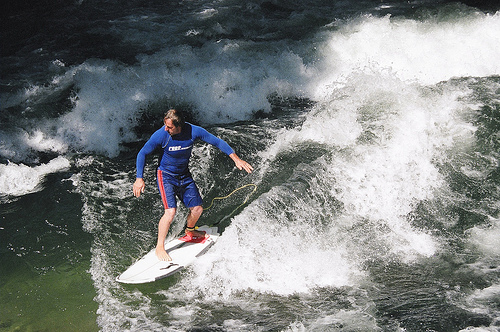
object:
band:
[184, 225, 199, 232]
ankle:
[182, 226, 196, 231]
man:
[131, 108, 254, 262]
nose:
[162, 125, 168, 133]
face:
[162, 115, 175, 135]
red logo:
[177, 230, 209, 244]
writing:
[170, 146, 178, 152]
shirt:
[134, 122, 236, 178]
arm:
[193, 126, 240, 163]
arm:
[134, 134, 159, 179]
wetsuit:
[134, 120, 236, 175]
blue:
[134, 121, 235, 178]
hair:
[163, 107, 184, 133]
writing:
[175, 144, 181, 151]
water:
[0, 0, 499, 331]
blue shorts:
[155, 168, 204, 210]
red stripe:
[156, 167, 169, 209]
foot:
[154, 248, 173, 262]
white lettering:
[166, 145, 173, 153]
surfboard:
[114, 223, 221, 284]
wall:
[211, 104, 366, 187]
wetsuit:
[155, 168, 207, 208]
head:
[162, 106, 182, 136]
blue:
[155, 168, 204, 210]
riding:
[0, 0, 498, 331]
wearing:
[134, 122, 236, 210]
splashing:
[0, 0, 499, 331]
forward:
[0, 0, 499, 331]